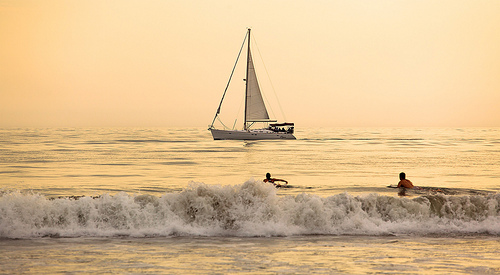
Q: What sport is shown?
A: Surfing.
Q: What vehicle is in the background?
A: Boat.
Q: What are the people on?
A: Surfboards.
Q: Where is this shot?
A: Ocean.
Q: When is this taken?
A: Daytime.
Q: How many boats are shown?
A: 1.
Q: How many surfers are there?
A: 2.